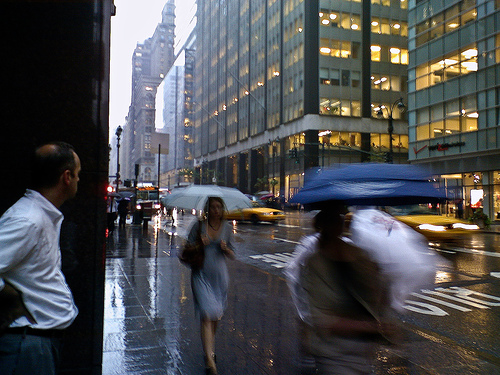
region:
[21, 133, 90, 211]
Head of a person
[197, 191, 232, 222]
Head of a person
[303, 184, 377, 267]
Head of a person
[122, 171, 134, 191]
Head of a person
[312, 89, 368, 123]
Window of a building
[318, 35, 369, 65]
Window of a building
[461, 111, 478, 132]
glass window on building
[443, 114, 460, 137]
glass window on building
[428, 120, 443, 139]
glass window on building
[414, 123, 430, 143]
glass window on building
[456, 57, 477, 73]
glass window on building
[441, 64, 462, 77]
glass window on building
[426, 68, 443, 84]
glass window on building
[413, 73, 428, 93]
glass window on building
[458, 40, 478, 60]
glass window on building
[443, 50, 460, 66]
glass window on building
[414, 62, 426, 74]
glass window on building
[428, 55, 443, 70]
glass window on building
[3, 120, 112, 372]
this is a man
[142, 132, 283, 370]
this is a woman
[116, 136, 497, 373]
the ground is wet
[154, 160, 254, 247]
this is an umbrella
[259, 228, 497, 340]
white writing on the ground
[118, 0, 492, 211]
buildings lining the street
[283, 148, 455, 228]
the umbrella is blue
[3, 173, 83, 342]
man wearing a white shirt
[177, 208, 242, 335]
woman wearing a dress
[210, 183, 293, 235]
this is a taxi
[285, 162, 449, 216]
a blue umbrella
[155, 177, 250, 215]
a white umbrella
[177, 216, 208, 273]
a woman's black bag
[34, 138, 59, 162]
bald spot on a man's head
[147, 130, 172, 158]
back side of a street sign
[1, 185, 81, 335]
a man's white shirt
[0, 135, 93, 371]
man standing on the side of a building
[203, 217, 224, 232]
black necklace on a woman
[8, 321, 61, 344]
a man's black belt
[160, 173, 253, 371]
Woman walking down a sidewalk.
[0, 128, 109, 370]
Man standing on side of building.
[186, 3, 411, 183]
Tall building with multiple stories.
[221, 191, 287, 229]
Yellow taxi cab driving down a street.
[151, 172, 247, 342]
woman holding a umbrella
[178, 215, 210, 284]
woman carrying a pocketbook